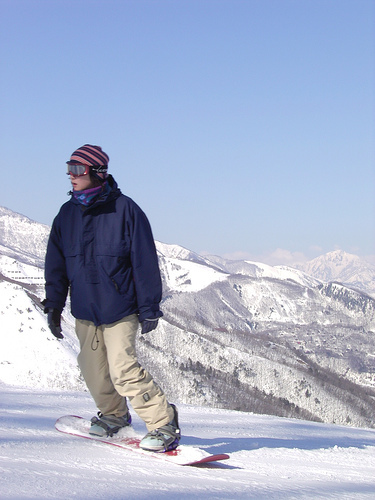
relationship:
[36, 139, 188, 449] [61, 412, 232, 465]
man on snowboard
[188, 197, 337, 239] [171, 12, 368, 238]
clouds are in sky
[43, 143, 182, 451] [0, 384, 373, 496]
man on top of slope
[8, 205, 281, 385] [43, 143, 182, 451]
hills are behind man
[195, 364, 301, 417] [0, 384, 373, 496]
trees are below slope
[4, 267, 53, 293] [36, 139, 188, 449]
row of squares on side of man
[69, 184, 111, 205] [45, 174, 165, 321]
scarf in jacket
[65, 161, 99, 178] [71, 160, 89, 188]
goggles are on face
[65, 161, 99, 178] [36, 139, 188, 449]
goggles are on man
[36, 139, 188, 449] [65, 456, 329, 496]
man on snow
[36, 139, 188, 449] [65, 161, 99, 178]
man has goggles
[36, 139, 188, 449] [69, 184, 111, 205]
man wears scarf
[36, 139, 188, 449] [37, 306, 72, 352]
man has right hand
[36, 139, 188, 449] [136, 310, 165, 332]
man has left hand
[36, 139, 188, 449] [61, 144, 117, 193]
man has head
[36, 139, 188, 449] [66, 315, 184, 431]
man has pants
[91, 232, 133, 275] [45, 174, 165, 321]
pocket on jacket